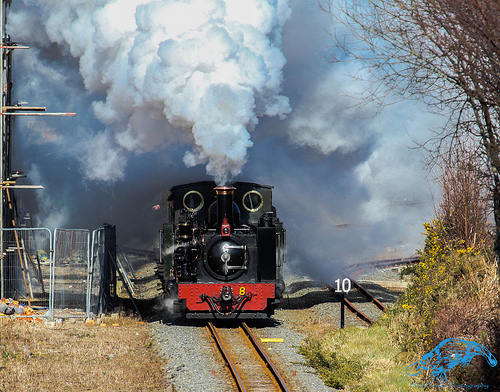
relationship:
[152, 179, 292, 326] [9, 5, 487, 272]
train blowing steam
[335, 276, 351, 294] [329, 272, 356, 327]
10 attached to pole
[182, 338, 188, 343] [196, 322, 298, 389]
rock next to track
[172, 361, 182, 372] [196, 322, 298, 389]
rock next to track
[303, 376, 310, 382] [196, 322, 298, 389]
rock next to track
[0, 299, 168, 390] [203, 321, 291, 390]
grass next to track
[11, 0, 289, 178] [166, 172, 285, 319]
smoke coming from train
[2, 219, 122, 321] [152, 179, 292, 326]
gate beside train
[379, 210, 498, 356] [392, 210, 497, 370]
flowers on bush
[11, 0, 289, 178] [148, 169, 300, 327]
smoke on train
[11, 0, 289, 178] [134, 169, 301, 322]
smoke from train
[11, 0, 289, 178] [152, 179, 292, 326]
smoke from train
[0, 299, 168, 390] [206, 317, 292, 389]
grass next to tracks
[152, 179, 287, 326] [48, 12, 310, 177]
train with smoke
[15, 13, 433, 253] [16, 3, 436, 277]
clouds in sky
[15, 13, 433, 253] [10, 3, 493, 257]
clouds in sky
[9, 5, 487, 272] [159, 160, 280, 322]
steam above train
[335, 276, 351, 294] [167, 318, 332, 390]
10 on track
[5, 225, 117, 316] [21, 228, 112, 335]
fence next to train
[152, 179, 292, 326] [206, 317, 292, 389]
train on tracks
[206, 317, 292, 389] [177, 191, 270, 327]
tracks in front of train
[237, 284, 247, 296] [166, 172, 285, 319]
number on train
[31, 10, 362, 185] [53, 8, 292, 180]
sky with smoke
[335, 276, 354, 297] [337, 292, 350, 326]
10 on a pole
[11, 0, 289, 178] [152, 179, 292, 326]
smoke of a train